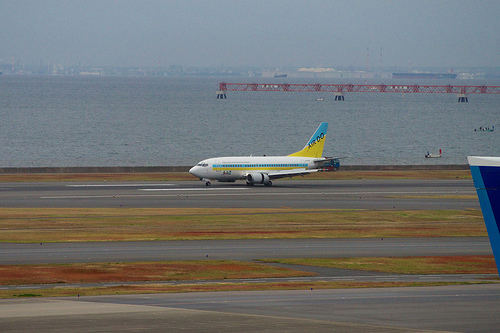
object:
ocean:
[7, 83, 489, 164]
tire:
[201, 178, 214, 188]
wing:
[270, 169, 320, 177]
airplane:
[187, 121, 350, 186]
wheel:
[263, 180, 276, 185]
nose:
[187, 163, 199, 178]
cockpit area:
[188, 158, 213, 178]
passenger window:
[238, 164, 247, 167]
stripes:
[207, 162, 313, 172]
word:
[307, 132, 325, 148]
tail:
[290, 117, 346, 174]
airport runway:
[2, 180, 478, 208]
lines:
[135, 188, 244, 191]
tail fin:
[287, 121, 328, 158]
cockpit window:
[196, 162, 206, 168]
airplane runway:
[0, 180, 497, 330]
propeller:
[245, 175, 252, 182]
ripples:
[24, 134, 93, 157]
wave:
[127, 113, 158, 136]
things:
[423, 150, 434, 158]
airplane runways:
[0, 176, 497, 330]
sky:
[1, 0, 497, 60]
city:
[2, 58, 498, 79]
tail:
[467, 153, 499, 285]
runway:
[2, 280, 498, 331]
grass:
[1, 206, 489, 243]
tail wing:
[310, 153, 349, 165]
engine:
[244, 170, 270, 186]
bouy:
[436, 150, 443, 158]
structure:
[213, 82, 498, 100]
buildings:
[137, 69, 149, 77]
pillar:
[360, 46, 381, 68]